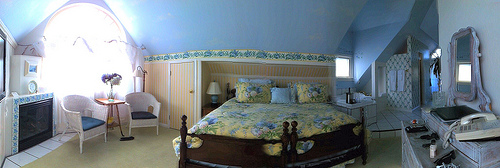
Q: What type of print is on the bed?
A: Floral.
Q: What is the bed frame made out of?
A: Wood.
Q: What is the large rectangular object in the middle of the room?
A: A bed.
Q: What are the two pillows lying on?
A: A bed.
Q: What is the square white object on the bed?
A: A pillow.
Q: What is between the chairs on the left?
A: Table.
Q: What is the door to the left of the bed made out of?
A: Wood.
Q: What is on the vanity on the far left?
A: Telephone.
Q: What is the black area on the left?
A: Fireplace.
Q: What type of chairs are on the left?
A: Wicker.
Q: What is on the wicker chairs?
A: Cushions.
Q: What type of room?
A: Bedroom.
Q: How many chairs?
A: Two.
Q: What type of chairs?
A: Wicker.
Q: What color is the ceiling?
A: Blue.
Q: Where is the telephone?
A: On the dresser.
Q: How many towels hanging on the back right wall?
A: Two.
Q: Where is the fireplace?
A: On the left.